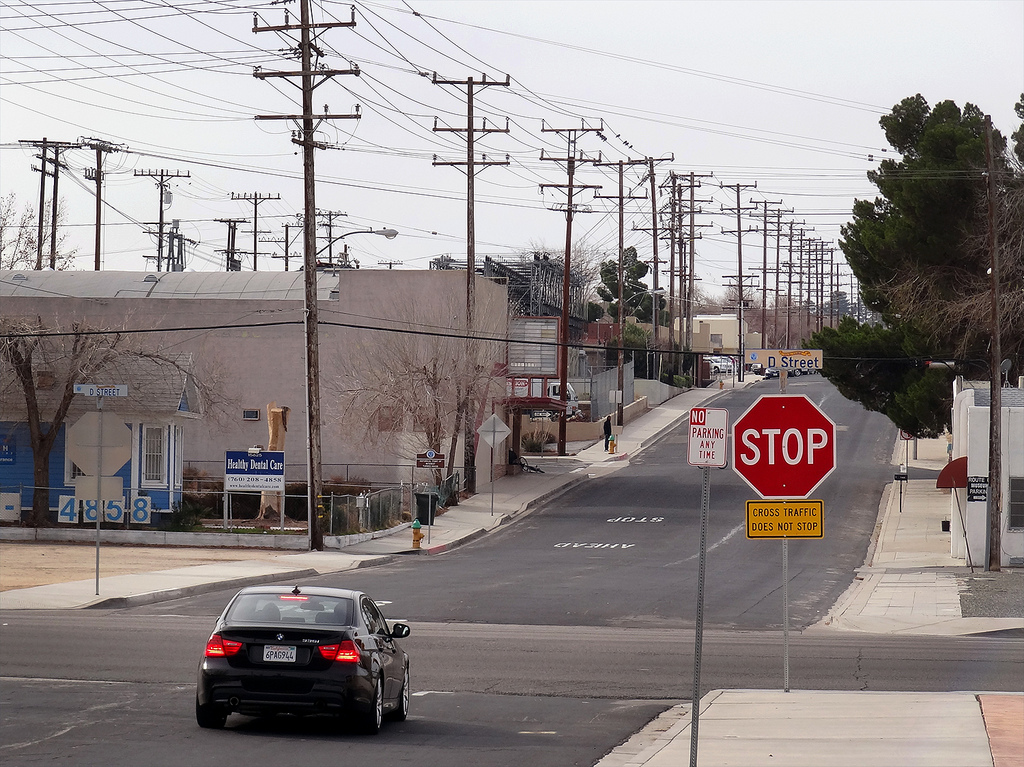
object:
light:
[307, 633, 368, 673]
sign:
[735, 495, 835, 546]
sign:
[220, 447, 291, 495]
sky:
[1, 0, 1024, 268]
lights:
[194, 632, 245, 665]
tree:
[785, 94, 1022, 575]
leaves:
[915, 188, 974, 256]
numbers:
[47, 490, 163, 534]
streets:
[0, 593, 1020, 699]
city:
[0, 0, 1024, 767]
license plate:
[250, 638, 303, 671]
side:
[625, 670, 1024, 767]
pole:
[687, 468, 718, 756]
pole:
[476, 412, 514, 517]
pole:
[539, 417, 546, 458]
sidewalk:
[604, 681, 1020, 763]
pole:
[589, 156, 645, 429]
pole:
[718, 177, 759, 392]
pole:
[249, 0, 366, 558]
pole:
[421, 61, 516, 506]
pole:
[530, 112, 609, 465]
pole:
[609, 158, 630, 434]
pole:
[623, 149, 676, 384]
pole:
[14, 137, 87, 276]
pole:
[129, 163, 194, 276]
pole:
[223, 185, 288, 281]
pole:
[770, 493, 802, 695]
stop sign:
[727, 388, 846, 505]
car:
[176, 563, 440, 753]